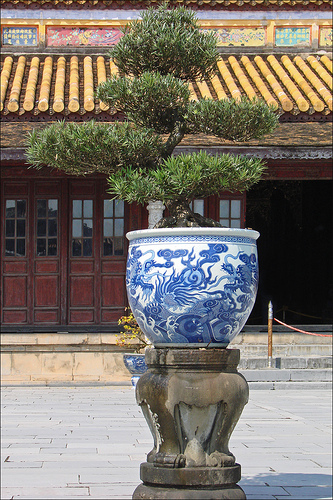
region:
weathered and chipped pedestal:
[123, 346, 274, 497]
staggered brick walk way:
[26, 410, 82, 486]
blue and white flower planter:
[119, 226, 263, 349]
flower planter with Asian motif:
[119, 226, 269, 348]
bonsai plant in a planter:
[23, 3, 286, 223]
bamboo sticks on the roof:
[277, 53, 329, 117]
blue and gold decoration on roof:
[2, 23, 41, 46]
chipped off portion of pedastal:
[171, 395, 226, 469]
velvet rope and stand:
[266, 300, 331, 369]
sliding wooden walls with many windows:
[7, 179, 116, 320]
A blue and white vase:
[120, 223, 268, 360]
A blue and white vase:
[118, 351, 153, 386]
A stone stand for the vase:
[124, 349, 266, 492]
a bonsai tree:
[16, 7, 259, 219]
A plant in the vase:
[120, 314, 152, 357]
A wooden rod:
[258, 292, 276, 372]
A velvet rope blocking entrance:
[268, 311, 329, 342]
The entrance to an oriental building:
[250, 177, 329, 333]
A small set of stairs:
[222, 338, 329, 388]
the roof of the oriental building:
[2, 49, 331, 157]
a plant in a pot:
[47, 7, 298, 338]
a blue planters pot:
[117, 199, 278, 370]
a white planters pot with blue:
[107, 221, 281, 389]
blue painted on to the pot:
[97, 217, 272, 361]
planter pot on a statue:
[30, 62, 289, 496]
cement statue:
[112, 328, 258, 495]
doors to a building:
[3, 148, 187, 334]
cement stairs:
[240, 304, 332, 372]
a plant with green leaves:
[48, 0, 302, 265]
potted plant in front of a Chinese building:
[0, 22, 321, 491]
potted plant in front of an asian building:
[4, 22, 321, 492]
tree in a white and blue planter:
[24, 21, 289, 350]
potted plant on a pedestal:
[25, 17, 276, 494]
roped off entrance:
[263, 292, 328, 378]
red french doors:
[2, 180, 97, 355]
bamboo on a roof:
[0, 47, 331, 123]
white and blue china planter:
[121, 223, 262, 348]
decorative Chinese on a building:
[4, 3, 330, 56]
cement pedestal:
[131, 343, 258, 499]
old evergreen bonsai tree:
[23, 3, 287, 238]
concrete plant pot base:
[115, 346, 263, 499]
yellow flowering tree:
[109, 297, 154, 355]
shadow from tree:
[215, 448, 330, 497]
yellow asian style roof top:
[1, 51, 331, 121]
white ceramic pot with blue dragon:
[118, 223, 261, 352]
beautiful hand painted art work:
[0, 18, 332, 55]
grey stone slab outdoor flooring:
[1, 383, 329, 499]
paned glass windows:
[1, 193, 249, 263]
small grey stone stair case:
[220, 336, 331, 388]